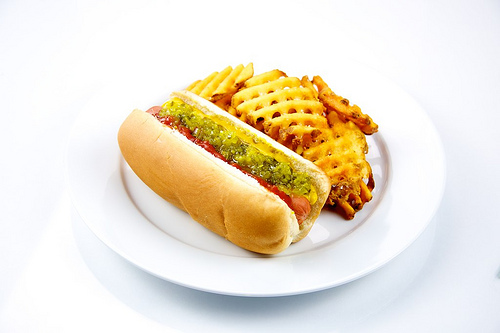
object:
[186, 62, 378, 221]
fries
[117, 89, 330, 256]
hot dog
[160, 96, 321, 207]
sauces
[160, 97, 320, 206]
mustard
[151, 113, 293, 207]
ketchup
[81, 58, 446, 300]
plate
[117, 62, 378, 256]
food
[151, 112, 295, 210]
relish toppings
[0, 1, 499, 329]
surface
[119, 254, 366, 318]
shadow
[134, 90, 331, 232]
ridge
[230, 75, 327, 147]
waffle fry